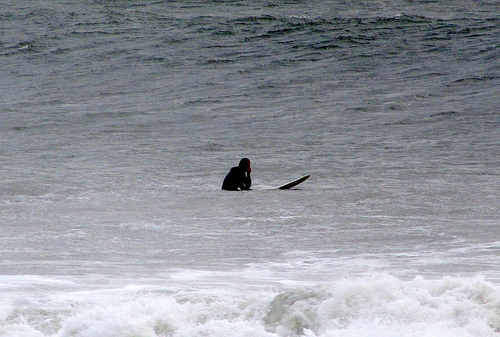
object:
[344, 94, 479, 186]
ripples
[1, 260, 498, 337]
white waves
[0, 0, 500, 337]
wave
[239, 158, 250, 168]
hair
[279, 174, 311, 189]
board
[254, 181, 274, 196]
foam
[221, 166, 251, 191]
wet suit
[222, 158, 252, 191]
man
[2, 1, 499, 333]
ocean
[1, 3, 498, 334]
water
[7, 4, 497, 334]
beach